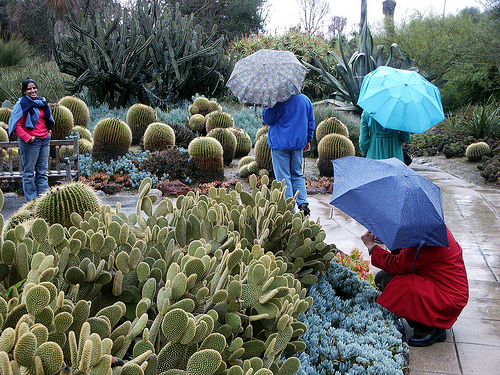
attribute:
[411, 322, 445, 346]
shoe — Black 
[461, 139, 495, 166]
cactus — Small 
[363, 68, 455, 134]
umbrella — light turquoise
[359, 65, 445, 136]
light-blue umbrella — light blue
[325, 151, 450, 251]
umbrella — blue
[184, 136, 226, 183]
cactus — small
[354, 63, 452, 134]
umbrella — Aqua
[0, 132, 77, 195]
bench — sparse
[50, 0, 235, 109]
cactus branches — slender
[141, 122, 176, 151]
cactus — small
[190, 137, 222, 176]
cactus — small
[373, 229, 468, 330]
coat — Red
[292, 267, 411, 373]
blue flowers — light blue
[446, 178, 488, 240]
pathway — square=stoned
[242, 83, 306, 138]
jacket — blue 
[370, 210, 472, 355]
jacket — red 